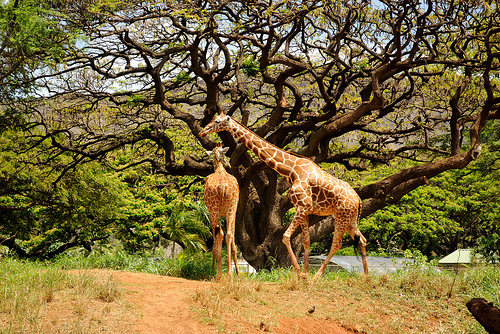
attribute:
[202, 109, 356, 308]
giraffes — together, standing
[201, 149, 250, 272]
giraffe — turned, large, baby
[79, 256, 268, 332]
path — red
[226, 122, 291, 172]
neck — long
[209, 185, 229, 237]
tail — long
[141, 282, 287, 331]
dirt — bare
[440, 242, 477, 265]
roof — yellow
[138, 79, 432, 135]
mountains — in distance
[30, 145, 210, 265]
tree — leafy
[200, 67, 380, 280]
giraffe — sideways, walking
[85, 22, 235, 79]
sky — white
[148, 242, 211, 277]
grass — green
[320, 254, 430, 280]
house — grey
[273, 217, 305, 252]
knee — white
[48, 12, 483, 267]
tree — bare, large, thick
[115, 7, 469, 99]
branches — black, curvy